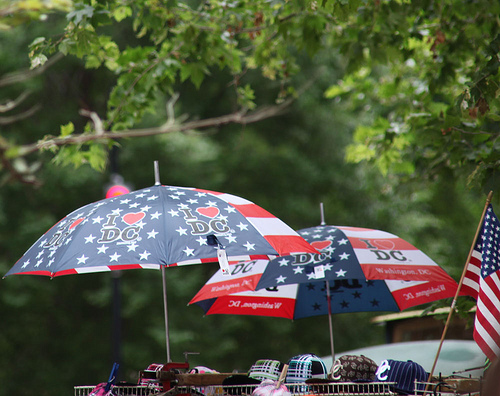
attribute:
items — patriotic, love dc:
[4, 161, 500, 363]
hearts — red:
[119, 206, 226, 223]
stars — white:
[163, 188, 192, 259]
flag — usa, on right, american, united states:
[452, 205, 500, 364]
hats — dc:
[324, 355, 428, 393]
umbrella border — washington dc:
[191, 267, 461, 317]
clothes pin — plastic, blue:
[277, 364, 290, 389]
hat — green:
[248, 380, 292, 395]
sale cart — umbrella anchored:
[54, 377, 493, 395]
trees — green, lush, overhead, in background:
[0, 0, 500, 191]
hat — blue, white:
[282, 354, 327, 392]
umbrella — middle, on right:
[186, 201, 471, 363]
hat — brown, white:
[306, 355, 379, 386]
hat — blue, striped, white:
[356, 359, 430, 391]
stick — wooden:
[421, 187, 493, 383]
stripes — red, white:
[337, 226, 457, 286]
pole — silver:
[160, 263, 172, 366]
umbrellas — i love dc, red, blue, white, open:
[3, 156, 463, 368]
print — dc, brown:
[353, 361, 364, 380]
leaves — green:
[355, 121, 418, 172]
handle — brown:
[422, 297, 456, 387]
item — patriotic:
[18, 185, 322, 278]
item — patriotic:
[194, 226, 458, 316]